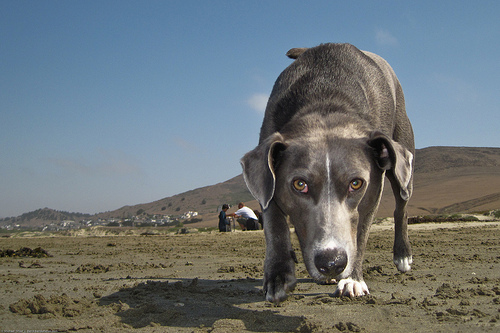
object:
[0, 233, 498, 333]
sand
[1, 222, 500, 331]
beach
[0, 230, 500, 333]
dirt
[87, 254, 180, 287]
part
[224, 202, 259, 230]
people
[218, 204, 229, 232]
people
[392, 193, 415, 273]
leg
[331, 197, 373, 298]
leg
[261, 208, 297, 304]
leg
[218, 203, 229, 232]
person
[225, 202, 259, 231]
person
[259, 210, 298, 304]
legs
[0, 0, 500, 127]
air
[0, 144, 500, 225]
hills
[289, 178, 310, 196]
eye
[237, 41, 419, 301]
dog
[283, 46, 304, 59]
gray tail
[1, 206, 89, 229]
mountain hillside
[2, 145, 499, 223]
mountain hillside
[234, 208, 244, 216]
sleeve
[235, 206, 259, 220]
shirt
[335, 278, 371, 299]
paw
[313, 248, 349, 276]
nose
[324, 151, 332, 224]
stripe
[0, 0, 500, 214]
ground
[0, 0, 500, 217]
sky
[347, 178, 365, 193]
eye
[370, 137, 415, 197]
ear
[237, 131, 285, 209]
ear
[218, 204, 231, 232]
child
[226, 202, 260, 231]
man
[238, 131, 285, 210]
right ear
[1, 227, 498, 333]
field